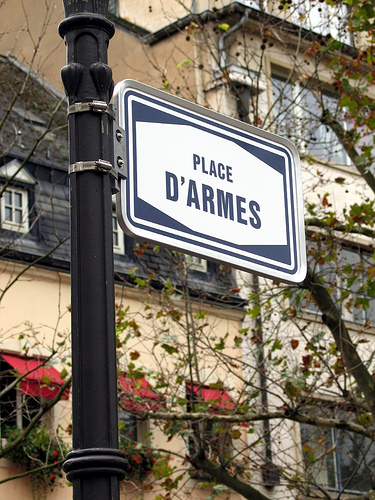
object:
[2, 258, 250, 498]
wall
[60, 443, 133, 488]
trim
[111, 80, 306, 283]
sign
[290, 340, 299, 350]
flowers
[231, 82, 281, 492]
gutter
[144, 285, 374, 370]
tree branch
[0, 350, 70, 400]
covering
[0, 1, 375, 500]
tree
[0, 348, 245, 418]
canopies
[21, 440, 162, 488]
flower baskets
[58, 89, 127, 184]
clamp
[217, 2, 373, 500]
building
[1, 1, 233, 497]
building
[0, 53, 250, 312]
roof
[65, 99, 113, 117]
bracket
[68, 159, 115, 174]
bracket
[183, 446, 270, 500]
branch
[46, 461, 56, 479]
red berries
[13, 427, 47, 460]
leaves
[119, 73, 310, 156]
trim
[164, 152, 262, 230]
place d'armes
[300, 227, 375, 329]
window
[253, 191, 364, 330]
floor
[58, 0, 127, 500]
pole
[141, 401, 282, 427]
branch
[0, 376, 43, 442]
window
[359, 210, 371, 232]
leeves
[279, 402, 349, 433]
branch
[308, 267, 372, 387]
plant